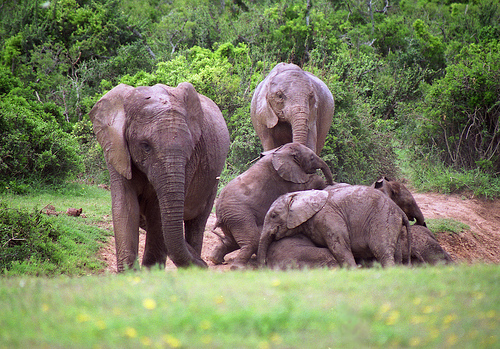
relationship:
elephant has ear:
[87, 82, 231, 271] [87, 81, 135, 180]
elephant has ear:
[87, 82, 231, 271] [176, 79, 203, 148]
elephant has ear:
[247, 60, 337, 182] [256, 73, 281, 131]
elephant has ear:
[211, 140, 333, 271] [270, 148, 312, 184]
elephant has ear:
[256, 183, 412, 267] [285, 188, 330, 229]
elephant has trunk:
[87, 82, 231, 271] [152, 163, 210, 270]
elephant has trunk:
[247, 60, 337, 182] [287, 111, 310, 147]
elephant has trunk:
[211, 140, 333, 271] [318, 158, 335, 186]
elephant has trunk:
[256, 183, 412, 267] [257, 226, 277, 265]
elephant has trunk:
[256, 183, 412, 267] [408, 190, 427, 228]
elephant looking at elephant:
[87, 82, 231, 271] [211, 140, 333, 271]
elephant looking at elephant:
[87, 82, 231, 271] [256, 183, 412, 267]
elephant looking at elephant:
[247, 60, 337, 182] [211, 140, 333, 271]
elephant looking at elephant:
[247, 60, 337, 182] [256, 183, 412, 267]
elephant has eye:
[87, 82, 231, 271] [138, 142, 151, 151]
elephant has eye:
[247, 60, 337, 182] [275, 91, 285, 100]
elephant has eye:
[211, 140, 333, 271] [308, 153, 315, 161]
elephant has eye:
[256, 183, 412, 267] [270, 211, 277, 220]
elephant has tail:
[211, 140, 333, 271] [211, 217, 229, 246]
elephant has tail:
[256, 183, 412, 267] [403, 212, 415, 265]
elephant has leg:
[211, 140, 333, 271] [223, 205, 259, 265]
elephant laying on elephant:
[211, 140, 333, 271] [256, 183, 412, 267]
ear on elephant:
[95, 81, 132, 178] [86, 79, 224, 270]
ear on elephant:
[178, 79, 204, 148] [86, 79, 224, 270]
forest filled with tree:
[7, 5, 483, 189] [403, 39, 498, 146]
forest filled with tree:
[7, 5, 483, 189] [246, 4, 340, 66]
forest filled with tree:
[7, 5, 483, 189] [365, 11, 447, 66]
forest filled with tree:
[7, 5, 483, 189] [114, 40, 258, 85]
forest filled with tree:
[7, 5, 483, 189] [57, 3, 143, 60]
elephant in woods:
[236, 46, 336, 199] [6, 6, 483, 208]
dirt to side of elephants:
[420, 189, 484, 271] [215, 145, 447, 266]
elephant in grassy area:
[87, 82, 231, 271] [8, 262, 498, 347]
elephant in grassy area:
[247, 60, 337, 182] [8, 262, 498, 347]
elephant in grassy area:
[211, 140, 333, 271] [8, 262, 498, 347]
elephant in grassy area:
[259, 182, 415, 259] [8, 262, 498, 347]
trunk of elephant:
[152, 163, 210, 270] [87, 82, 231, 271]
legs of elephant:
[209, 209, 264, 269] [211, 140, 333, 271]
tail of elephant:
[210, 211, 227, 235] [211, 140, 333, 271]